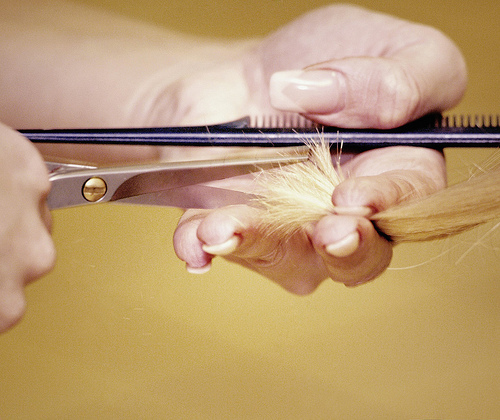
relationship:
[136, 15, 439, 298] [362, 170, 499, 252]
hairdresser hand trimming blonde hair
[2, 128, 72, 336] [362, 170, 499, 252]
hairdresser hand trimming blonde hair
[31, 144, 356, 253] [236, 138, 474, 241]
scissors cutting hair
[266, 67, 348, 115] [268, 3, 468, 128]
fingernail on finger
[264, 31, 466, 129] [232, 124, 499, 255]
finger holding hair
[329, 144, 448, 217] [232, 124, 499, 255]
finger holding hair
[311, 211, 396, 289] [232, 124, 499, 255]
finger holding hair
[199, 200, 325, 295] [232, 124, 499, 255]
finger holding hair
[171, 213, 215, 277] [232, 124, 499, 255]
finger holding hair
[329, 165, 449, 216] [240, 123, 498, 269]
finger holding hair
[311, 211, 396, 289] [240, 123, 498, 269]
finger holding hair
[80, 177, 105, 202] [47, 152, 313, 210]
brass screw in scissors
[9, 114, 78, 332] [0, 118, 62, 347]
knuckles on hand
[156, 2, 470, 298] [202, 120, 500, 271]
hairdresser hand cutting blond hair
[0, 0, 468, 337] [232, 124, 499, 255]
beautician cutting hair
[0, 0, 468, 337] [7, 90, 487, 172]
beautician holds comb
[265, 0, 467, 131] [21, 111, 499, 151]
finger on comb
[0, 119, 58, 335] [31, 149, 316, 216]
hairdresser hand controls scissors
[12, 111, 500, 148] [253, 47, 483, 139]
black comb between finger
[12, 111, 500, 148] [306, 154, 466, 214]
black comb between finger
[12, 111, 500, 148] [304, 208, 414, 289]
black comb between finger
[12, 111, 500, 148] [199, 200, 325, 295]
black comb between finger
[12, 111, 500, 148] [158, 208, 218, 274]
black comb between finger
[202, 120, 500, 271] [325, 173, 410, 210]
blond hair between fingertip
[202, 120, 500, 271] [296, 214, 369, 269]
blond hair between fingertip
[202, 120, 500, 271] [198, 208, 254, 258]
blond hair between fingertip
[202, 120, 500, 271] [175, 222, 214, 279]
blond hair between fingertip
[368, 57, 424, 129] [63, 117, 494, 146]
knuckle steadies comb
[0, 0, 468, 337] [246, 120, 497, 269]
beautician trimming blond hair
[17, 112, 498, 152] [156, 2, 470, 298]
black comb in hairdresser hand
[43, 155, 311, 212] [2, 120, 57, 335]
scissors in hand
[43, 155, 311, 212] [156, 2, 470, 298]
scissors in hairdresser hand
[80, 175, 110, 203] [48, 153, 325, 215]
brass screw in scissors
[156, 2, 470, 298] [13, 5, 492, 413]
hairdresser hand on beauticians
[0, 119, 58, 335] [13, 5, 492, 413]
hairdresser hand on beauticians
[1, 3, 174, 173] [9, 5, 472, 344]
arm on beautician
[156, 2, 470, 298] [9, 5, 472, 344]
hairdresser hand on beautician